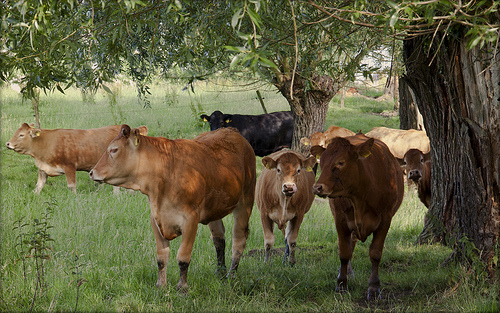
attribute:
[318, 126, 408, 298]
cow — black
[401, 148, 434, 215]
cow — Brown 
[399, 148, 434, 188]
head — out 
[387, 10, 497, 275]
tree — behind 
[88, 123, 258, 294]
cows — facing outwards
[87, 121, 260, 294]
cow — facing outwards, Brown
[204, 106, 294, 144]
black cow —  black , back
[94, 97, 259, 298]
cow — black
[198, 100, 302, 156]
cow — black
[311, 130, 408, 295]
brown cow — brown 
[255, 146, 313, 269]
cow — Brown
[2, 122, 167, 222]
cow — brown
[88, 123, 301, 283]
cow — brown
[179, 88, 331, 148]
cow — brown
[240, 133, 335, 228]
cow — brown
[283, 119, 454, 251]
cow — brown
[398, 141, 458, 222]
cow — brown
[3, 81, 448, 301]
cattle — black , orange, herd 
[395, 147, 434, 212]
cow — brown 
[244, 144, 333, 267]
cow — brown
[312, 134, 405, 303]
three cows — Three 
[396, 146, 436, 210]
cow — Brown 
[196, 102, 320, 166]
cow — black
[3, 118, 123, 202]
cow —  brown, left front half 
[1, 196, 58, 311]
weeds — Tall 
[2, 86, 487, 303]
grass — green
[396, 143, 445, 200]
calf —  brown 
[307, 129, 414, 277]
cow — Eight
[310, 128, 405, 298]
cow — brown 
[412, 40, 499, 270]
tree trunk — thick tree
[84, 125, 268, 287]
face — left half , her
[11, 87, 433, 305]
cows — brown , group 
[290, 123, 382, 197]
head —  inquisitive cow